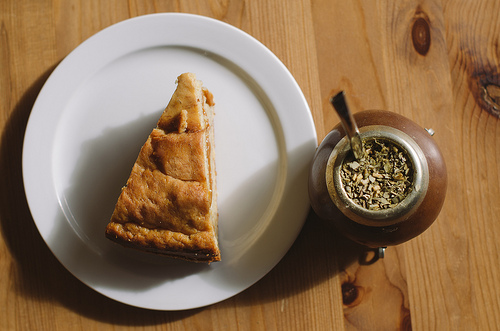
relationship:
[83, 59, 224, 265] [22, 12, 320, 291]
pie on a plate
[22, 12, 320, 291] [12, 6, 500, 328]
plate on table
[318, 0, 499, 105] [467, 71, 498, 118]
wood has some knots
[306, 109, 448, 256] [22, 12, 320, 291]
bowl near plate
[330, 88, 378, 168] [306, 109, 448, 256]
spoon in bowl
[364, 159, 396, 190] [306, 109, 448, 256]
seeds in bowl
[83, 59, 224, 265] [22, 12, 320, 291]
pie on plate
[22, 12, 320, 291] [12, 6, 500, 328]
plate on a table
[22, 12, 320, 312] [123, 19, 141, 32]
plate has a rim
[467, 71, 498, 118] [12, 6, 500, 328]
knots in table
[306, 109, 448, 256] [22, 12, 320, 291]
bowl next to plate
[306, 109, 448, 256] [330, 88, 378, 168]
bowl has a spoon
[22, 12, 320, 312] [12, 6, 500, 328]
plate on table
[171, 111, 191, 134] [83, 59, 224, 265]
crumb of pie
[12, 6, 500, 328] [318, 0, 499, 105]
table made of wood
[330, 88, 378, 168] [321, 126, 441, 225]
spoon in bowl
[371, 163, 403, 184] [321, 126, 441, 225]
oats in bowl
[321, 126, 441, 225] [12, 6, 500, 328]
bowl on table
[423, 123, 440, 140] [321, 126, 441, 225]
silver handle on bowl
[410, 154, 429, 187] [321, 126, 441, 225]
silver rim on bowl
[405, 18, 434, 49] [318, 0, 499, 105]
spot in wood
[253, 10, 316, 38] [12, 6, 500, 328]
stripes on table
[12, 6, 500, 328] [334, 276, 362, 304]
table with oval marking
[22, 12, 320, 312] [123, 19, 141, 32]
plate with rim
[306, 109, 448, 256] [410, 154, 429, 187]
bowl with silver rim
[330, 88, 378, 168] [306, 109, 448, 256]
utensil inside bowl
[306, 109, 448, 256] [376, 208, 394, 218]
bowl with metal